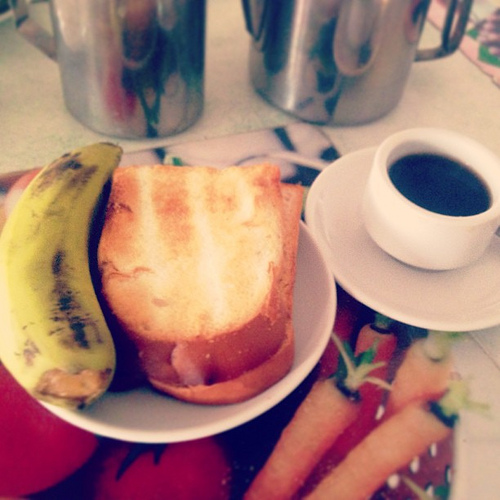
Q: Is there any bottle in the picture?
A: No, there are no bottles.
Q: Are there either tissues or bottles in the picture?
A: No, there are no bottles or tissues.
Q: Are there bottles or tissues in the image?
A: No, there are no bottles or tissues.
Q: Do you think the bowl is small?
A: Yes, the bowl is small.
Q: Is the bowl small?
A: Yes, the bowl is small.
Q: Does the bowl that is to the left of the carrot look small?
A: Yes, the bowl is small.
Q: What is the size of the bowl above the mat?
A: The bowl is small.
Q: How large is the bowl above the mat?
A: The bowl is small.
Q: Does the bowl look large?
A: No, the bowl is small.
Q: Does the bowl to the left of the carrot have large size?
A: No, the bowl is small.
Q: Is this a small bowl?
A: Yes, this is a small bowl.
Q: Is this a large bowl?
A: No, this is a small bowl.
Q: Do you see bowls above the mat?
A: Yes, there is a bowl above the mat.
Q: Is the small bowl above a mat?
A: Yes, the bowl is above a mat.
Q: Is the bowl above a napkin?
A: No, the bowl is above a mat.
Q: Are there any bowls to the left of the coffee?
A: Yes, there is a bowl to the left of the coffee.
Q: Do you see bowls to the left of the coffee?
A: Yes, there is a bowl to the left of the coffee.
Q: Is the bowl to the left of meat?
A: No, the bowl is to the left of the coffee.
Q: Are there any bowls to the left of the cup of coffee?
A: Yes, there is a bowl to the left of the cup.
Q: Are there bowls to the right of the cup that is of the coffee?
A: No, the bowl is to the left of the cup.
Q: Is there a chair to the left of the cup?
A: No, there is a bowl to the left of the cup.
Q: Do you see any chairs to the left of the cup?
A: No, there is a bowl to the left of the cup.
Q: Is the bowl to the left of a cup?
A: Yes, the bowl is to the left of a cup.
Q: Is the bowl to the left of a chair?
A: No, the bowl is to the left of a cup.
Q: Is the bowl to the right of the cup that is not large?
A: No, the bowl is to the left of the cup.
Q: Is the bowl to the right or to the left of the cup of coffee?
A: The bowl is to the left of the cup.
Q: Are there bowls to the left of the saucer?
A: Yes, there is a bowl to the left of the saucer.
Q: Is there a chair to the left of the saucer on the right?
A: No, there is a bowl to the left of the saucer.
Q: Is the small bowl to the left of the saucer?
A: Yes, the bowl is to the left of the saucer.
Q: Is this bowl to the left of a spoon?
A: No, the bowl is to the left of the saucer.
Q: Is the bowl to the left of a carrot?
A: Yes, the bowl is to the left of a carrot.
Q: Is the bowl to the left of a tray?
A: No, the bowl is to the left of a carrot.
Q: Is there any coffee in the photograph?
A: Yes, there is coffee.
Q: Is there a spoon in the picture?
A: No, there are no spoons.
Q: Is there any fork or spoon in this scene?
A: No, there are no spoons or forks.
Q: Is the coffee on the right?
A: Yes, the coffee is on the right of the image.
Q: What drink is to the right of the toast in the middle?
A: The drink is coffee.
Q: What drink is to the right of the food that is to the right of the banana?
A: The drink is coffee.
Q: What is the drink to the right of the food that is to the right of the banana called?
A: The drink is coffee.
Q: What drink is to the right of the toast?
A: The drink is coffee.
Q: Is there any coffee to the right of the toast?
A: Yes, there is coffee to the right of the toast.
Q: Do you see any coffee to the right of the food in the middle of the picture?
A: Yes, there is coffee to the right of the toast.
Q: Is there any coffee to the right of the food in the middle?
A: Yes, there is coffee to the right of the toast.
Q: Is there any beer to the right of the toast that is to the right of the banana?
A: No, there is coffee to the right of the toast.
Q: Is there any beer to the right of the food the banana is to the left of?
A: No, there is coffee to the right of the toast.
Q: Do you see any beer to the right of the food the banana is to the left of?
A: No, there is coffee to the right of the toast.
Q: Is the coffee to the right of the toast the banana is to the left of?
A: Yes, the coffee is to the right of the toast.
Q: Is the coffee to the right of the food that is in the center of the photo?
A: Yes, the coffee is to the right of the toast.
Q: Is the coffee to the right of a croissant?
A: No, the coffee is to the right of the toast.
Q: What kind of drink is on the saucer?
A: The drink is coffee.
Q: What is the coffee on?
A: The coffee is on the saucer.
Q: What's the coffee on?
A: The coffee is on the saucer.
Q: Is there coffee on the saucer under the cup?
A: Yes, there is coffee on the saucer.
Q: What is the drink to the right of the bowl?
A: The drink is coffee.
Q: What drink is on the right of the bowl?
A: The drink is coffee.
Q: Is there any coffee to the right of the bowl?
A: Yes, there is coffee to the right of the bowl.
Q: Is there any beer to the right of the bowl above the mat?
A: No, there is coffee to the right of the bowl.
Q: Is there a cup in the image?
A: Yes, there is a cup.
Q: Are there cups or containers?
A: Yes, there is a cup.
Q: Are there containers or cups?
A: Yes, there is a cup.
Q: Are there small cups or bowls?
A: Yes, there is a small cup.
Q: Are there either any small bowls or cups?
A: Yes, there is a small cup.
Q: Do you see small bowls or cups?
A: Yes, there is a small cup.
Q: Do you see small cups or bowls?
A: Yes, there is a small cup.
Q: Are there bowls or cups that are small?
A: Yes, the cup is small.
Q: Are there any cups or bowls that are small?
A: Yes, the cup is small.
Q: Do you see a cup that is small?
A: Yes, there is a small cup.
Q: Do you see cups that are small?
A: Yes, there is a cup that is small.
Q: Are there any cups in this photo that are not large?
A: Yes, there is a small cup.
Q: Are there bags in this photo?
A: No, there are no bags.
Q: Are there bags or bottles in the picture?
A: No, there are no bags or bottles.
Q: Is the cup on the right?
A: Yes, the cup is on the right of the image.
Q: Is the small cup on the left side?
A: No, the cup is on the right of the image.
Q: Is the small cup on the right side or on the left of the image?
A: The cup is on the right of the image.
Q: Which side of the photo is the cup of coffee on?
A: The cup is on the right of the image.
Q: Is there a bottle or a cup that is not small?
A: No, there is a cup but it is small.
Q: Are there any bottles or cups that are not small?
A: No, there is a cup but it is small.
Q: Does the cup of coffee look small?
A: Yes, the cup is small.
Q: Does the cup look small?
A: Yes, the cup is small.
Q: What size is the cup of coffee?
A: The cup is small.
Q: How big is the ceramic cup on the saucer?
A: The cup is small.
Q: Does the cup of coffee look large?
A: No, the cup is small.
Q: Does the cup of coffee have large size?
A: No, the cup is small.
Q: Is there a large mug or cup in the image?
A: No, there is a cup but it is small.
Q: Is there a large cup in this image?
A: No, there is a cup but it is small.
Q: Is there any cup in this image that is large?
A: No, there is a cup but it is small.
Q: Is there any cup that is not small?
A: No, there is a cup but it is small.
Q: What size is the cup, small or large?
A: The cup is small.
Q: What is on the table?
A: The cup is on the table.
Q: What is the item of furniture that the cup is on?
A: The piece of furniture is a table.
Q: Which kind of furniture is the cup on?
A: The cup is on the table.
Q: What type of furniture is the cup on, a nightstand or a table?
A: The cup is on a table.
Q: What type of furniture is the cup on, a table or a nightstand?
A: The cup is on a table.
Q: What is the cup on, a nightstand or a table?
A: The cup is on a table.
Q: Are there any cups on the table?
A: Yes, there is a cup on the table.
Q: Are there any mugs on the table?
A: No, there is a cup on the table.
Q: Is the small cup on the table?
A: Yes, the cup is on the table.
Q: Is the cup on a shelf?
A: No, the cup is on the table.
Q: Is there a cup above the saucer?
A: Yes, there is a cup above the saucer.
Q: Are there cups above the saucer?
A: Yes, there is a cup above the saucer.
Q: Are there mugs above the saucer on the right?
A: No, there is a cup above the saucer.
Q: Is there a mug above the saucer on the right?
A: No, there is a cup above the saucer.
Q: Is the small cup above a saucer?
A: Yes, the cup is above a saucer.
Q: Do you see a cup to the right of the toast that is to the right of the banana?
A: Yes, there is a cup to the right of the toast.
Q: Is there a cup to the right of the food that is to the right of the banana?
A: Yes, there is a cup to the right of the toast.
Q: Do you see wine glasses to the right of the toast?
A: No, there is a cup to the right of the toast.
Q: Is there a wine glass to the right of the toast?
A: No, there is a cup to the right of the toast.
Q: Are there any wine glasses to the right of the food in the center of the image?
A: No, there is a cup to the right of the toast.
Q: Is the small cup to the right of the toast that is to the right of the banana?
A: Yes, the cup is to the right of the toast.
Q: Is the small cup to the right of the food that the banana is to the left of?
A: Yes, the cup is to the right of the toast.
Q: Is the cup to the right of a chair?
A: No, the cup is to the right of the toast.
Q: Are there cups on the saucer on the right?
A: Yes, there is a cup on the saucer.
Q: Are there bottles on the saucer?
A: No, there is a cup on the saucer.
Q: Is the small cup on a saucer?
A: Yes, the cup is on a saucer.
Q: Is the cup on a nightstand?
A: No, the cup is on a saucer.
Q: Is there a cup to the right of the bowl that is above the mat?
A: Yes, there is a cup to the right of the bowl.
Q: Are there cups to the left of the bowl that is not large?
A: No, the cup is to the right of the bowl.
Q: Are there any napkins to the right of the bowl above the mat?
A: No, there is a cup to the right of the bowl.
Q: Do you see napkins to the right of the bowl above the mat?
A: No, there is a cup to the right of the bowl.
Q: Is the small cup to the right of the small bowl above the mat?
A: Yes, the cup is to the right of the bowl.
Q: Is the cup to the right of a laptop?
A: No, the cup is to the right of the bowl.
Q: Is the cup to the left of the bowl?
A: No, the cup is to the right of the bowl.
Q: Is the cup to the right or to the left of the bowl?
A: The cup is to the right of the bowl.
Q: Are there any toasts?
A: Yes, there is a toast.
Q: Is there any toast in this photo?
A: Yes, there is a toast.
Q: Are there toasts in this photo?
A: Yes, there is a toast.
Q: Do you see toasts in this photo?
A: Yes, there is a toast.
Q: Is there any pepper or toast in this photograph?
A: Yes, there is a toast.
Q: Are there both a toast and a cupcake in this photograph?
A: No, there is a toast but no cupcakes.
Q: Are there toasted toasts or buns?
A: Yes, there is a toasted toast.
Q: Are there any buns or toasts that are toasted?
A: Yes, the toast is toasted.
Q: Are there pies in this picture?
A: No, there are no pies.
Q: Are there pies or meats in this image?
A: No, there are no pies or meats.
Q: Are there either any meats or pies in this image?
A: No, there are no pies or meats.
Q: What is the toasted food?
A: The food is a toast.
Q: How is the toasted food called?
A: The food is a toast.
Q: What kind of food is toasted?
A: The food is a toast.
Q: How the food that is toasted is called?
A: The food is a toast.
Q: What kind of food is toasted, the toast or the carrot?
A: The toast is toasted.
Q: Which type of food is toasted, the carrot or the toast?
A: The toast is toasted.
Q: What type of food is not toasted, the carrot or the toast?
A: The carrot is not toasted.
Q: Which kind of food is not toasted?
A: The food is a carrot.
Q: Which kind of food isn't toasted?
A: The food is a carrot.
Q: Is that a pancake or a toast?
A: That is a toast.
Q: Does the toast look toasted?
A: Yes, the toast is toasted.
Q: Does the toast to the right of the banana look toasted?
A: Yes, the toast is toasted.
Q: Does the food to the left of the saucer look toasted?
A: Yes, the toast is toasted.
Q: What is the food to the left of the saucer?
A: The food is a toast.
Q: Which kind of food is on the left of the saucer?
A: The food is a toast.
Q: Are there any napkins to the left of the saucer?
A: No, there is a toast to the left of the saucer.